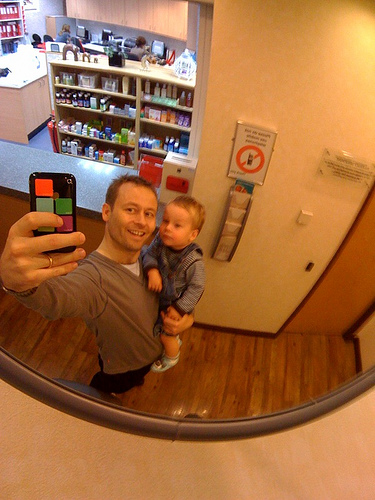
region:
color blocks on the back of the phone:
[25, 164, 77, 257]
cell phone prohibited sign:
[230, 117, 267, 189]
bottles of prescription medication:
[52, 59, 191, 173]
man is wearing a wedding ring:
[38, 250, 57, 270]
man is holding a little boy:
[100, 156, 230, 362]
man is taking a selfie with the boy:
[6, 159, 254, 372]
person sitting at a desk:
[127, 31, 152, 61]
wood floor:
[201, 339, 282, 397]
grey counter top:
[16, 142, 100, 186]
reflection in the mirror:
[9, 331, 369, 460]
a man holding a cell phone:
[17, 165, 90, 287]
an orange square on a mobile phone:
[32, 175, 56, 199]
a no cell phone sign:
[225, 117, 273, 190]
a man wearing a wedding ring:
[40, 251, 58, 272]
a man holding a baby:
[90, 167, 211, 388]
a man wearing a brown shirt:
[45, 243, 179, 380]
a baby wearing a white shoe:
[145, 341, 188, 380]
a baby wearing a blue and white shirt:
[144, 231, 214, 323]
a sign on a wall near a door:
[303, 137, 373, 212]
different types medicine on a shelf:
[48, 62, 136, 145]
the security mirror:
[2, 3, 373, 449]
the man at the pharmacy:
[9, 152, 217, 410]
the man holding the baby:
[16, 141, 221, 386]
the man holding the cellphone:
[13, 159, 115, 297]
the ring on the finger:
[35, 250, 59, 267]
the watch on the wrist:
[0, 279, 39, 300]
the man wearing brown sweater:
[26, 256, 178, 368]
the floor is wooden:
[204, 338, 350, 396]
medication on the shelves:
[59, 70, 176, 158]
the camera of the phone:
[64, 176, 73, 186]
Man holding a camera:
[23, 175, 78, 253]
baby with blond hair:
[157, 189, 208, 242]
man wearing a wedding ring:
[42, 254, 56, 269]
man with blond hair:
[100, 178, 163, 235]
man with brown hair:
[79, 246, 169, 378]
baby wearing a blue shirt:
[151, 245, 197, 316]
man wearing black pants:
[80, 359, 146, 398]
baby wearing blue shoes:
[147, 350, 186, 374]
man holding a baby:
[103, 182, 207, 381]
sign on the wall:
[232, 115, 267, 188]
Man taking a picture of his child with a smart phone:
[7, 124, 251, 402]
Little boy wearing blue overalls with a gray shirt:
[148, 187, 221, 383]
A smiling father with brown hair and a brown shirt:
[2, 151, 166, 406]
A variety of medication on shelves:
[34, 1, 210, 171]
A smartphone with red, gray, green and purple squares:
[22, 159, 86, 260]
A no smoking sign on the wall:
[219, 105, 273, 191]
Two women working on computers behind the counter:
[30, 0, 202, 63]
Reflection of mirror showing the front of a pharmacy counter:
[0, 9, 371, 454]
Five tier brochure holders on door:
[209, 172, 262, 276]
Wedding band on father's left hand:
[1, 141, 116, 322]